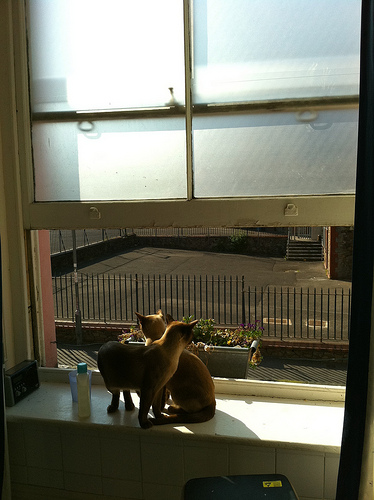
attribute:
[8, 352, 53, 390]
black radio — small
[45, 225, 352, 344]
fence — black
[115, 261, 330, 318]
fence — wrought iron 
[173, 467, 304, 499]
trash can — black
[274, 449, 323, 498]
tile — white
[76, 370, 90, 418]
bottle — white 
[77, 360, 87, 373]
blue lid — blue 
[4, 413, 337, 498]
tiles — white 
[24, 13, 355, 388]
window — open 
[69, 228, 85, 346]
post — large , silver 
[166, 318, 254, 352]
flowers — purple 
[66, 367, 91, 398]
liquid — clear 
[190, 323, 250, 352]
plants — green , brown 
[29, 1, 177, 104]
paper — white 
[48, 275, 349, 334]
fence — metal 